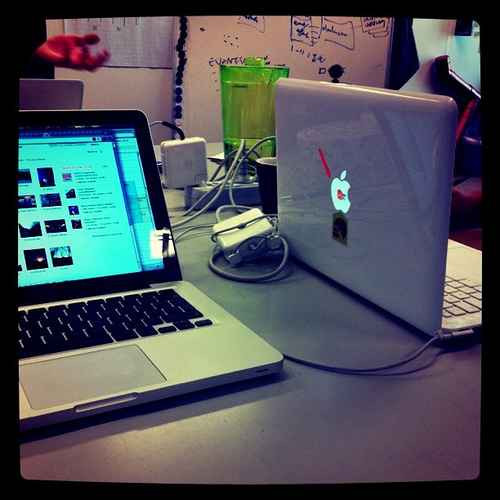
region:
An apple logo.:
[304, 135, 371, 225]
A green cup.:
[202, 45, 297, 207]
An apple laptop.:
[264, 68, 488, 346]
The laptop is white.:
[248, 72, 488, 344]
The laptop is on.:
[18, 105, 293, 441]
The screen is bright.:
[12, 107, 182, 305]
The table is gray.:
[273, 392, 465, 477]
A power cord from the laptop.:
[272, 316, 474, 382]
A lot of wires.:
[151, 117, 298, 289]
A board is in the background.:
[175, 16, 393, 171]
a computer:
[200, 76, 468, 493]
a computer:
[208, 40, 396, 350]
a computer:
[253, 74, 495, 336]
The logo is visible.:
[308, 157, 373, 277]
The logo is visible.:
[323, 173, 370, 245]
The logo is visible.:
[326, 155, 356, 208]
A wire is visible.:
[311, 316, 409, 458]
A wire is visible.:
[329, 362, 393, 411]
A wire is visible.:
[305, 336, 382, 404]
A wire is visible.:
[306, 285, 397, 407]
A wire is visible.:
[336, 360, 378, 436]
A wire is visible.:
[349, 363, 367, 384]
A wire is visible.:
[334, 326, 420, 416]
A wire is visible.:
[354, 336, 404, 403]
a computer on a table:
[171, 82, 453, 384]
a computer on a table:
[215, 46, 400, 313]